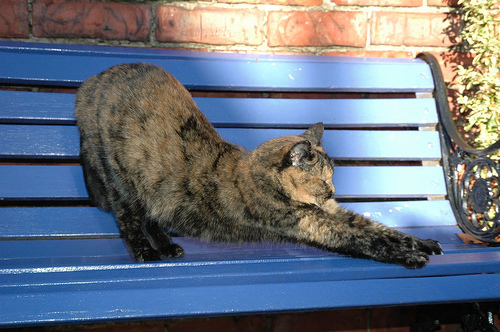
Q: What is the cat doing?
A: Stretching.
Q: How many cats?
A: One.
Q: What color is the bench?
A: Blue.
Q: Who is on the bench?
A: The cat.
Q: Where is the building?
A: Behind bench.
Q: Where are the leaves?
A: Beside bench.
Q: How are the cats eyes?
A: Closed.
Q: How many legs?
A: Four.